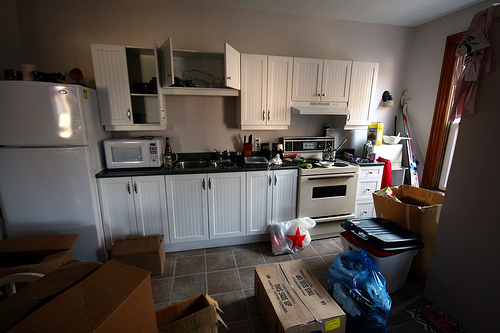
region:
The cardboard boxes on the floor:
[6, 226, 281, 331]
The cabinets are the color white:
[105, 176, 287, 246]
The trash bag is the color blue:
[322, 237, 393, 325]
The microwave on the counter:
[99, 131, 164, 173]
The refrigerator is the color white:
[0, 71, 109, 276]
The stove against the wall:
[276, 135, 363, 242]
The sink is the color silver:
[174, 151, 244, 176]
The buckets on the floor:
[338, 211, 424, 301]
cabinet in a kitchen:
[90, 48, 166, 133]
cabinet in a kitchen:
[158, 40, 236, 90]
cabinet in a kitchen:
[237, 52, 290, 129]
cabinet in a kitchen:
[347, 60, 378, 126]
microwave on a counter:
[97, 130, 165, 171]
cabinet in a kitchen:
[105, 176, 170, 232]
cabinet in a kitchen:
[165, 172, 246, 237]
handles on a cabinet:
[193, 167, 221, 203]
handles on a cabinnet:
[262, 174, 284, 189]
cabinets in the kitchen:
[86, 39, 388, 255]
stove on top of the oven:
[291, 155, 358, 170]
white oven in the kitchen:
[295, 165, 358, 239]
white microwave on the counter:
[99, 132, 165, 168]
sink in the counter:
[174, 145, 233, 168]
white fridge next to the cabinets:
[0, 77, 108, 264]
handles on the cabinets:
[199, 175, 213, 191]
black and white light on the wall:
[378, 86, 395, 107]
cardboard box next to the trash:
[250, 256, 349, 331]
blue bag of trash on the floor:
[326, 250, 393, 332]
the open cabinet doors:
[160, 40, 237, 96]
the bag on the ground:
[263, 218, 315, 255]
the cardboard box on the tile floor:
[255, 257, 338, 332]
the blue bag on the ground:
[326, 248, 391, 325]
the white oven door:
[295, 171, 354, 233]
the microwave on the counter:
[98, 135, 164, 170]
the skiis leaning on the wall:
[397, 91, 422, 190]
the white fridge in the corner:
[0, 80, 104, 245]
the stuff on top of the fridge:
[0, 63, 88, 88]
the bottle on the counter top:
[160, 129, 177, 171]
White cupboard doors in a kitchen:
[97, 178, 170, 253]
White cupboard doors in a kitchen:
[165, 173, 247, 242]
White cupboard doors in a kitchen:
[246, 171, 303, 235]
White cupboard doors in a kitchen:
[90, 45, 167, 132]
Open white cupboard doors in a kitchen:
[160, 36, 242, 95]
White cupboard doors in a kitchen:
[240, 50, 293, 133]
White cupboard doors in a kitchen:
[290, 54, 352, 103]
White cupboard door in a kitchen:
[346, 58, 379, 127]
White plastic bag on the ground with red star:
[264, 215, 324, 255]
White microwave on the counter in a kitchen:
[103, 133, 163, 170]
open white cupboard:
[87, 32, 168, 134]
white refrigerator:
[4, 77, 117, 266]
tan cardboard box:
[252, 257, 357, 332]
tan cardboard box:
[5, 260, 163, 332]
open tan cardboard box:
[0, 225, 87, 288]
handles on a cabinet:
[109, 174, 152, 201]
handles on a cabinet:
[196, 176, 221, 197]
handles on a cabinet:
[260, 163, 278, 194]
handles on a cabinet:
[256, 96, 284, 132]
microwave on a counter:
[98, 132, 160, 169]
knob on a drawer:
[360, 166, 375, 176]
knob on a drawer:
[356, 180, 371, 190]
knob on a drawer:
[357, 198, 370, 215]